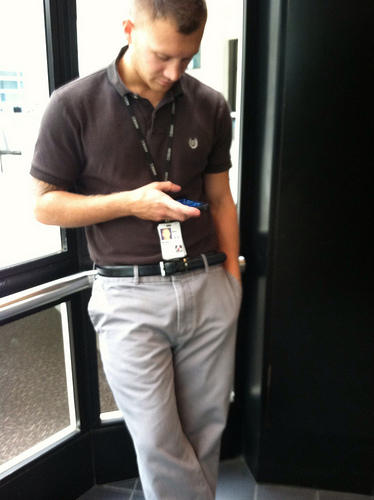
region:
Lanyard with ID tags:
[121, 95, 189, 262]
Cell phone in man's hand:
[169, 196, 210, 212]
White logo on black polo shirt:
[187, 135, 198, 149]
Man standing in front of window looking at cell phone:
[29, 0, 242, 498]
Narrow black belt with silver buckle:
[92, 247, 228, 277]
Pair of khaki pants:
[87, 251, 245, 498]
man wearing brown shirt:
[17, 4, 294, 341]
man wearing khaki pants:
[1, 10, 257, 496]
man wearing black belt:
[8, 10, 237, 311]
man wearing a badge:
[15, 10, 264, 372]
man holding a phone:
[36, 5, 265, 310]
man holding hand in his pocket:
[29, 1, 275, 370]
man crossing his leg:
[19, 6, 268, 322]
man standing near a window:
[18, 9, 275, 310]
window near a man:
[12, 324, 74, 441]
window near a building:
[8, 11, 44, 97]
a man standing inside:
[81, 27, 223, 200]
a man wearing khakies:
[57, 189, 292, 495]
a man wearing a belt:
[111, 220, 222, 306]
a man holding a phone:
[128, 178, 267, 267]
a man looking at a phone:
[142, 173, 225, 260]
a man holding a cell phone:
[122, 202, 218, 246]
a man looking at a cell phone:
[160, 178, 226, 229]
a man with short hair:
[79, 22, 264, 253]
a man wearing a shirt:
[91, 71, 223, 270]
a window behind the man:
[5, 4, 85, 281]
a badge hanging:
[119, 93, 189, 263]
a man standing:
[34, 2, 245, 493]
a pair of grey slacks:
[87, 261, 246, 496]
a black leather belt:
[96, 249, 226, 278]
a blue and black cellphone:
[166, 187, 213, 214]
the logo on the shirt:
[185, 133, 200, 151]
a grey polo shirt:
[28, 48, 234, 255]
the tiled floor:
[72, 458, 362, 496]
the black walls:
[244, 1, 373, 483]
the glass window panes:
[0, 2, 246, 479]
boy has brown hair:
[125, 5, 236, 56]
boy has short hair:
[126, 1, 236, 17]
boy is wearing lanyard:
[109, 78, 206, 185]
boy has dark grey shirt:
[70, 76, 222, 238]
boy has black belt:
[63, 238, 231, 319]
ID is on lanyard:
[155, 219, 187, 268]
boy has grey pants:
[94, 267, 211, 497]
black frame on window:
[0, 5, 95, 302]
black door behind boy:
[253, 17, 370, 404]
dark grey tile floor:
[205, 464, 253, 498]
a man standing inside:
[85, 34, 281, 315]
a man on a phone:
[46, 154, 254, 329]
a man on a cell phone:
[80, 159, 258, 295]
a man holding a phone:
[81, 153, 269, 337]